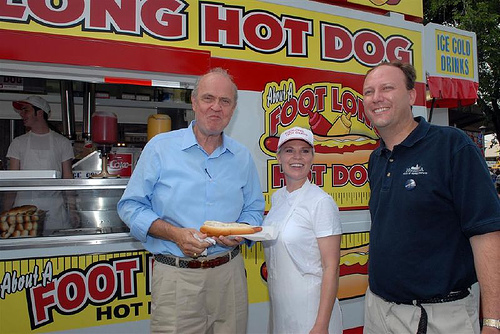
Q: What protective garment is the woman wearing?
A: Apron.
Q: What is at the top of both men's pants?
A: Belts.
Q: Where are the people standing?
A: In front of a hot dog truck.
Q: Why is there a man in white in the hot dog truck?
A: He works there.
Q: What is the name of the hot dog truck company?
A: About a foot long hot dog.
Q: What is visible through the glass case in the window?
A: Hot dog buns.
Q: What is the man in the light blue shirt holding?
A: A hot dog.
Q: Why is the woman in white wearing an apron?
A: For work.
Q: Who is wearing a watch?
A: The man in the dark blue shirt.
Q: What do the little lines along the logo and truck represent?
A: Ruler.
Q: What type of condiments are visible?
A: Ketchup and mustard.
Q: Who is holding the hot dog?
A: The man on the left.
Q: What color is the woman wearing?
A: White.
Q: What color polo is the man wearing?
A: Navy blue.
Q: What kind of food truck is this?
A: Hot dog.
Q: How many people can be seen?
A: 4.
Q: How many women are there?
A: 1.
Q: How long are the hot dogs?
A: 1 foot.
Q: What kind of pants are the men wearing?
A: Khakis.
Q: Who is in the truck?
A: Employee.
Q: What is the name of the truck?
A: About a foot hot dogs.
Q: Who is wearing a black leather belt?
A: The man on right.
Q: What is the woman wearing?
A: Uniform.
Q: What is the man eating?
A: A hot dog.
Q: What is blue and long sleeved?
A: The shirt.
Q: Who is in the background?
A: A worker.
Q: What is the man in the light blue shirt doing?
A: Eating a hotdog.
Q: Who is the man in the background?
A: A food server.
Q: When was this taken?
A: During the day.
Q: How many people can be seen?
A: Four.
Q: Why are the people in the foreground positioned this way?
A: They are posing for a photo.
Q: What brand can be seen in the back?
A: Coca-Cola.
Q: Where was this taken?
A: In front of a food truck.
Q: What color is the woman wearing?
A: White.